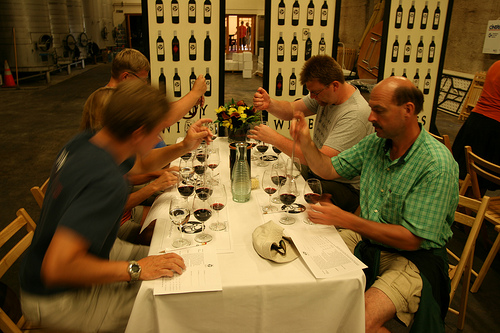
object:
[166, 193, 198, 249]
glass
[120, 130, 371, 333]
table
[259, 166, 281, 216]
glass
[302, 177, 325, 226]
glass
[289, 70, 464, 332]
person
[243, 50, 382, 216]
person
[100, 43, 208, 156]
person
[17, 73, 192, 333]
person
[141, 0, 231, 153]
divider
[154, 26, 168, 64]
picture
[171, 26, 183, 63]
picture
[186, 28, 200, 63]
picture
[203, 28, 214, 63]
picture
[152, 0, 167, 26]
picture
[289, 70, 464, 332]
man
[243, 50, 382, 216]
man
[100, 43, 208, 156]
man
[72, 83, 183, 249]
woman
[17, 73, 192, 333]
man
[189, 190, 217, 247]
glass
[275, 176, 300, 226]
glass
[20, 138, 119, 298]
top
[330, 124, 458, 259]
shirt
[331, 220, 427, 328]
shorts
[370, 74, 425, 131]
head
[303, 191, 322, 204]
red wine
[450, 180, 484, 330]
chair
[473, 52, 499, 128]
top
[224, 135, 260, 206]
vase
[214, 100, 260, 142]
flowers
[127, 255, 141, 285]
watch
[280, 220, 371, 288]
paper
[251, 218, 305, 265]
ball cap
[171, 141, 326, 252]
drinks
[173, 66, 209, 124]
hand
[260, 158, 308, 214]
glasses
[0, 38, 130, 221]
floor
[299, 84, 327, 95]
glasses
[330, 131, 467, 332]
clothes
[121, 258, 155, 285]
wrist